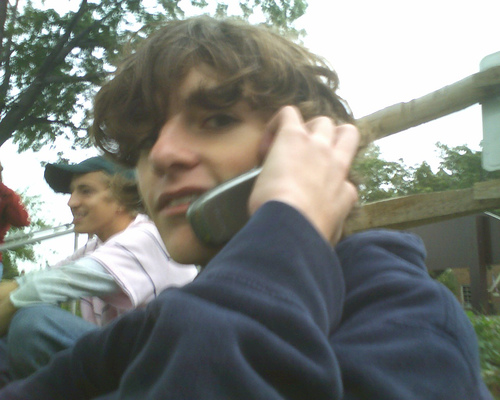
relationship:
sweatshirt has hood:
[90, 212, 475, 398] [341, 220, 430, 281]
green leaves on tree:
[3, 0, 306, 150] [0, 0, 310, 231]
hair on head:
[81, 10, 371, 241] [89, 19, 361, 264]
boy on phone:
[2, 10, 494, 397] [185, 160, 262, 250]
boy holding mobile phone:
[2, 15, 494, 398] [185, 164, 262, 247]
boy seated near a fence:
[2, 10, 494, 397] [315, 57, 497, 222]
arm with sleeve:
[0, 105, 362, 397] [113, 203, 340, 399]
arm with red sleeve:
[2, 180, 34, 240] [2, 177, 36, 245]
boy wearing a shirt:
[0, 155, 199, 397] [79, 230, 211, 312]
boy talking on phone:
[2, 15, 494, 398] [185, 160, 262, 250]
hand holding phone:
[266, 99, 364, 248] [186, 135, 352, 257]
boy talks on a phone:
[2, 15, 494, 398] [180, 165, 280, 246]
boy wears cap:
[0, 155, 199, 397] [45, 153, 137, 194]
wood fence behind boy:
[310, 68, 499, 257] [2, 15, 494, 398]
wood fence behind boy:
[310, 68, 499, 257] [0, 143, 202, 329]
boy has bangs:
[2, 15, 494, 398] [91, 38, 261, 168]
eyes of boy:
[126, 107, 244, 151] [2, 15, 494, 398]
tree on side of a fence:
[4, 0, 304, 165] [6, 47, 498, 317]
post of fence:
[355, 64, 498, 154] [332, 75, 499, 307]